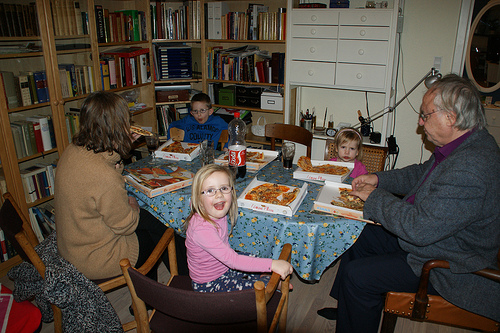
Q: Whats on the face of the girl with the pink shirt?
A: Glasses.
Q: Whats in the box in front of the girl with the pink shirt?
A: A pizza.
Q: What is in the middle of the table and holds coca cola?
A: A bottle.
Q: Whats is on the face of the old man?
A: Glasses.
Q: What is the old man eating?
A: Pizza.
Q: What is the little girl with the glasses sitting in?
A: A chair.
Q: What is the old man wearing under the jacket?
A: A purple turtle neck.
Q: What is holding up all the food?
A: The table.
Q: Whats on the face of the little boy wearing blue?
A: Glasses.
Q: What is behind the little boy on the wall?
A: Bookcase.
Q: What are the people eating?
A: Pizza.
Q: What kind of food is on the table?
A: Pizza.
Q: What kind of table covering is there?
A: A tablecloth.